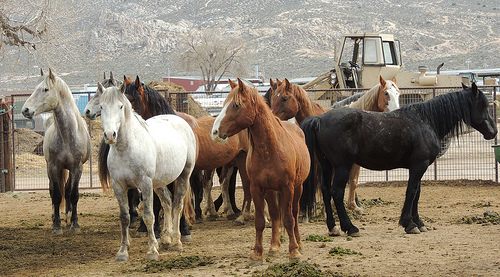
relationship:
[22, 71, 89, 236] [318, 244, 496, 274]
white horse in pasture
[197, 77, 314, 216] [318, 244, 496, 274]
brown horse in pasture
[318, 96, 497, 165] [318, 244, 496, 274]
black horse in pasture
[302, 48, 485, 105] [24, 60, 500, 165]
gray tractor on farm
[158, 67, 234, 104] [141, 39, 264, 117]
red and gray barn at a distance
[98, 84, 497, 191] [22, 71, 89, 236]
metal gate used to contain horse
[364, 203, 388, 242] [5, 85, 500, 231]
dirt in corral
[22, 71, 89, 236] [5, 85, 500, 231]
horse manure in corral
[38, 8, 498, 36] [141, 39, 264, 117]
mountain at a distance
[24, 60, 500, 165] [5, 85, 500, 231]
fence keeping horses in pen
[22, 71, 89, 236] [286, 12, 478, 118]
horse in front of tractor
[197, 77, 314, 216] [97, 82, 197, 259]
brown horse and white horse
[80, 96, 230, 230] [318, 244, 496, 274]
white horse in pasture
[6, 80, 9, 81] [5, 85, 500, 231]
grey horse in corral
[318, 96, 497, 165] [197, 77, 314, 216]
black horse and brown horse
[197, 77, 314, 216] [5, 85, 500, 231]
brown horse in corral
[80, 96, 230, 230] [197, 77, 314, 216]
white horse and brown horse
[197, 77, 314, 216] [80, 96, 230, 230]
brown horse and white horse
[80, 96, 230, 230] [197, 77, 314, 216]
white horse with brown horse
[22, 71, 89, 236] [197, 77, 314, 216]
gray horse with brown horse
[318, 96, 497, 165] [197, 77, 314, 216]
black horse with brown horse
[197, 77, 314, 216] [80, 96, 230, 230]
brown horse with white horse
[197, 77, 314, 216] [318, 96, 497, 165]
brown horse with black horse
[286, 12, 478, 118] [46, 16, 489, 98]
bulldozer in background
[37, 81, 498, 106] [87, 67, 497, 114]
large chain fence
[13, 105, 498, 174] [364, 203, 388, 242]
large area of dirt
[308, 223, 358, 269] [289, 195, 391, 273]
patches of green horse poop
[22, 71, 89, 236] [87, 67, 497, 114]
horse standing near fence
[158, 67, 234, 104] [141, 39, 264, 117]
red and gray barn in distance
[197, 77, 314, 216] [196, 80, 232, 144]
brown horse with white stripe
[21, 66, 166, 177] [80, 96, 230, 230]
three horses are all white horse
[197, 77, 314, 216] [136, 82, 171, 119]
brown horse with black mane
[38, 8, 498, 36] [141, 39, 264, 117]
mountain in distance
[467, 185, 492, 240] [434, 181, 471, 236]
horse poop on ground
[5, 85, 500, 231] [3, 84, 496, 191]
horses in fence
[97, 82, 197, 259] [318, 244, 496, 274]
horse in pasture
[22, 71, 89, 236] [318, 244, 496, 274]
horse in pasture